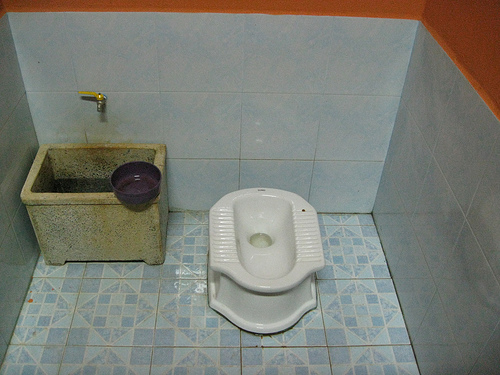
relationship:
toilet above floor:
[208, 175, 330, 333] [67, 280, 173, 374]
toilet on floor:
[208, 175, 330, 333] [67, 280, 173, 374]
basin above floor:
[35, 141, 176, 264] [67, 280, 173, 374]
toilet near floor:
[208, 175, 330, 333] [67, 280, 173, 374]